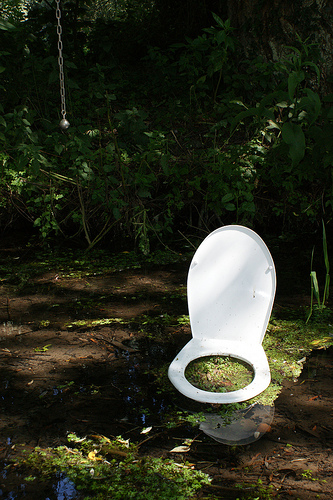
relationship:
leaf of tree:
[118, 198, 134, 209] [65, 107, 146, 247]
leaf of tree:
[114, 144, 130, 163] [0, 0, 331, 247]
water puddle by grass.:
[32, 357, 162, 435] [43, 442, 199, 499]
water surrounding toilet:
[0, 284, 333, 498] [166, 224, 276, 406]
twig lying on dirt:
[87, 332, 127, 353] [1, 245, 331, 497]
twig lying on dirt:
[42, 335, 71, 343] [1, 245, 331, 497]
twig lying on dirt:
[14, 354, 58, 363] [1, 245, 331, 497]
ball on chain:
[58, 117, 74, 134] [48, 1, 86, 111]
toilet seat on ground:
[161, 329, 274, 405] [4, 236, 329, 497]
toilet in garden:
[164, 224, 273, 409] [64, 301, 318, 476]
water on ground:
[41, 284, 333, 497] [4, 236, 329, 497]